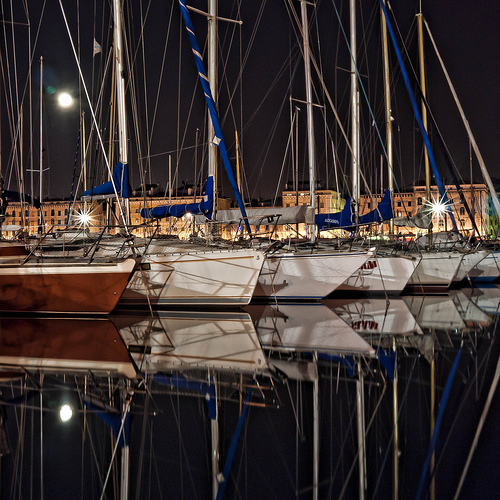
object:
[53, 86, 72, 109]
light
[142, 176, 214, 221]
cloth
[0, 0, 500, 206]
sky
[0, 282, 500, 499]
reflections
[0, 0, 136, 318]
boats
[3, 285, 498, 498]
water